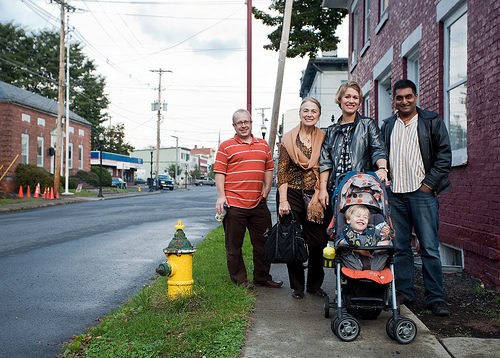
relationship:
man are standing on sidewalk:
[379, 79, 451, 314] [243, 194, 455, 356]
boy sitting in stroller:
[336, 205, 391, 269] [326, 170, 417, 343]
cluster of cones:
[15, 180, 61, 200] [18, 184, 54, 197]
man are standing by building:
[379, 79, 451, 314] [345, 1, 500, 298]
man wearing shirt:
[216, 109, 278, 286] [213, 134, 273, 209]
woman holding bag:
[277, 97, 327, 297] [261, 210, 307, 264]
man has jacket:
[379, 79, 447, 314] [383, 107, 449, 192]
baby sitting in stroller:
[336, 205, 391, 269] [326, 170, 417, 343]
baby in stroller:
[336, 205, 391, 269] [326, 170, 417, 343]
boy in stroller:
[336, 205, 391, 269] [326, 170, 417, 343]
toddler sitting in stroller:
[336, 205, 391, 269] [326, 170, 417, 343]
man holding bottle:
[216, 109, 278, 286] [213, 202, 228, 222]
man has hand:
[379, 79, 447, 314] [418, 183, 434, 200]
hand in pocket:
[418, 183, 434, 200] [412, 190, 437, 213]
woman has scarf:
[277, 97, 327, 297] [284, 123, 324, 167]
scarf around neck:
[284, 123, 324, 167] [300, 123, 317, 140]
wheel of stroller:
[331, 312, 361, 341] [326, 170, 417, 343]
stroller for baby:
[326, 170, 417, 343] [336, 205, 391, 269]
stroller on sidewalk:
[326, 170, 417, 343] [243, 194, 455, 356]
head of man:
[231, 109, 254, 136] [216, 109, 278, 286]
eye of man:
[237, 120, 241, 128] [216, 109, 278, 286]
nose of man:
[241, 121, 245, 129] [216, 109, 278, 286]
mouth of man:
[239, 128, 249, 132] [216, 109, 278, 286]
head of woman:
[300, 98, 320, 125] [277, 97, 327, 297]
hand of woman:
[278, 198, 290, 217] [277, 97, 327, 297]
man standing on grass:
[216, 109, 278, 286] [69, 223, 248, 357]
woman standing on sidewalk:
[277, 97, 327, 297] [243, 194, 455, 356]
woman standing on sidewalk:
[319, 82, 389, 304] [243, 194, 455, 356]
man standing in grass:
[216, 109, 278, 286] [69, 223, 248, 357]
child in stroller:
[336, 205, 391, 269] [326, 170, 417, 343]